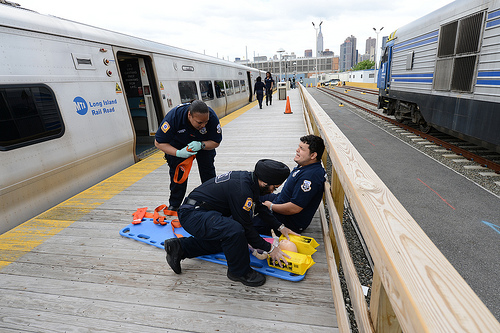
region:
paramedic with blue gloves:
[153, 84, 225, 190]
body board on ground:
[113, 199, 318, 302]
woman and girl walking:
[254, 71, 279, 107]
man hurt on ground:
[259, 121, 336, 240]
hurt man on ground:
[265, 126, 330, 250]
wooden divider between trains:
[302, 73, 469, 331]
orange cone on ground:
[283, 94, 294, 120]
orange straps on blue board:
[131, 200, 183, 235]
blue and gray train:
[366, 0, 498, 145]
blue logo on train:
[70, 89, 128, 122]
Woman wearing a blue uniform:
[143, 96, 227, 211]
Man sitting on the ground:
[259, 132, 326, 229]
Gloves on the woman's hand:
[168, 130, 213, 164]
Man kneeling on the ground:
[162, 149, 292, 292]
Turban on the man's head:
[248, 154, 289, 189]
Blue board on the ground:
[116, 195, 324, 298]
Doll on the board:
[237, 217, 298, 269]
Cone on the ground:
[278, 92, 297, 122]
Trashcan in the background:
[273, 76, 290, 106]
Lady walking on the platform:
[243, 74, 269, 114]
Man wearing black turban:
[159, 155, 296, 286]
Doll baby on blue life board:
[249, 229, 299, 261]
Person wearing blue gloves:
[155, 99, 223, 208]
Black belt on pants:
[179, 195, 209, 210]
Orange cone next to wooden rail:
[282, 93, 293, 116]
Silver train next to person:
[0, 0, 271, 247]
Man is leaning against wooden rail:
[255, 133, 324, 230]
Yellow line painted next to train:
[0, 86, 277, 268]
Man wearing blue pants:
[163, 156, 288, 288]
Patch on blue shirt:
[300, 178, 313, 193]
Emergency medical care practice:
[117, 100, 323, 280]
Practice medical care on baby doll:
[123, 96, 323, 283]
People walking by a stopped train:
[247, 68, 277, 108]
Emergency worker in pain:
[253, 136, 323, 234]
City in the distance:
[207, 19, 377, 86]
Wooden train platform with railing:
[0, 66, 490, 328]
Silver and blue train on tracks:
[318, 0, 495, 192]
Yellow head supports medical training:
[268, 230, 318, 282]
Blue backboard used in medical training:
[120, 206, 310, 281]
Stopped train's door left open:
[116, 51, 166, 158]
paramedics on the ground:
[135, 90, 327, 291]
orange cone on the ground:
[275, 95, 288, 123]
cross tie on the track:
[466, 160, 481, 172]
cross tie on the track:
[455, 158, 465, 167]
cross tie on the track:
[430, 148, 447, 156]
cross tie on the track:
[417, 139, 427, 151]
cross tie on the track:
[405, 133, 417, 138]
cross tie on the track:
[389, 124, 396, 134]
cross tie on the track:
[474, 170, 496, 177]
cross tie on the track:
[447, 154, 464, 165]